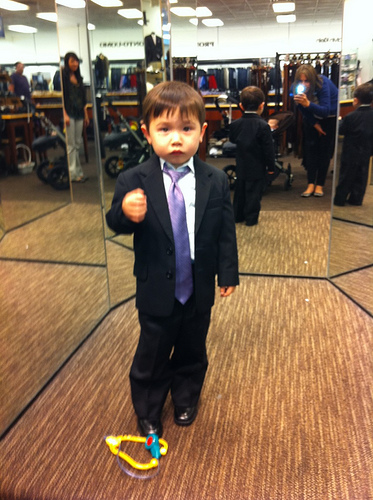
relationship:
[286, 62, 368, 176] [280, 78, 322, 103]
woman with camera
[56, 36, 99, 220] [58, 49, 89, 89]
reflection of woman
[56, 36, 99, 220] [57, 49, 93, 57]
reflection in mirror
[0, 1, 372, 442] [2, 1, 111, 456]
mirror with panel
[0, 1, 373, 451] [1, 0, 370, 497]
mirror in room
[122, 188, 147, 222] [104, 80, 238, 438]
hand on boy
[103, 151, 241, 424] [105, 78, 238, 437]
suit on boy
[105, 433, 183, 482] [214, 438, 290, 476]
toy on ground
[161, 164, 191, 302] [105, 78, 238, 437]
tie on boy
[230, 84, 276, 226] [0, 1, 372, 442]
reflection in mirror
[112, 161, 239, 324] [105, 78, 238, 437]
jacket on boy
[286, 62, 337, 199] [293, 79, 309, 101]
reflection of woman holding camera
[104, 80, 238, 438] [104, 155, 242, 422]
boy trying on a tuxedo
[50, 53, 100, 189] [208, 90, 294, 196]
woman standing by stroller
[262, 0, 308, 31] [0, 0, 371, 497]
lights are in store